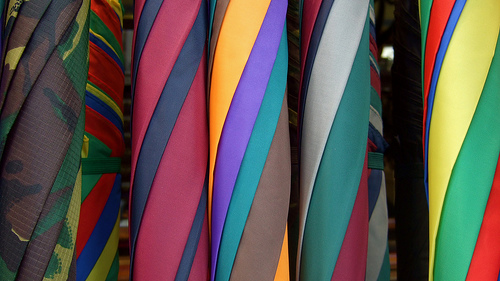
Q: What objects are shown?
A: Flags.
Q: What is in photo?
A: Umbrellas.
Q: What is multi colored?
A: Many umbrellas.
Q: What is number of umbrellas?
A: Six.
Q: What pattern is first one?
A: Camo.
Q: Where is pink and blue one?
A: Third from left.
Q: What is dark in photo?
A: Background.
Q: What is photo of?
A: Umbrellas in many colors.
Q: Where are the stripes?
A: On umbrellas.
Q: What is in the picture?
A: Brown yellow purple blue twisted cloth pieces.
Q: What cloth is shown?
A: Twisted green and brown camouflaged cloth.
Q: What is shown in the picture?
A: Multi colored tie.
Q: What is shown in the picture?
A: Multi colored tie.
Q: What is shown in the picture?
A: Multi colored tie.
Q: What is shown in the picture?
A: Multi colored tie.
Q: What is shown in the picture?
A: Multi colored tie.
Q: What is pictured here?
A: Neckties.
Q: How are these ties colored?
A: Multi colored.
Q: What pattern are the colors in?
A: Stripes.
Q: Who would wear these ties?
A: Businessmen.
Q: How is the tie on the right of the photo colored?
A: Yellow, red, blue and green.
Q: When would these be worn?
A: Going to work.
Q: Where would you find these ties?
A: Department store.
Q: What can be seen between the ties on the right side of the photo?
A: An open space.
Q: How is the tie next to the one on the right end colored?
A: Blue, red, white and teal.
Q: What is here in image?
A: Fabrics.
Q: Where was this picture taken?
A: A market.